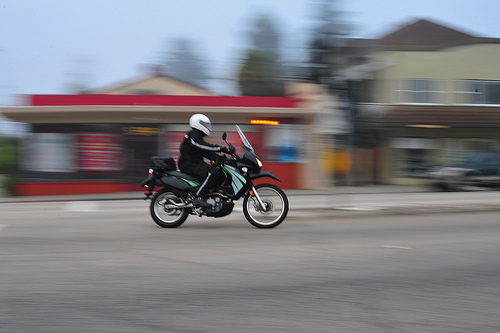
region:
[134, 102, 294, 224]
motorcyclist in the road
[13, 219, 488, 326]
paved road where motorcyclist is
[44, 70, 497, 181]
buildings along side of street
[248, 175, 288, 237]
front tire of a bike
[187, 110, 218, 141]
helmet on a rider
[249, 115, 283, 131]
blurry lights on a building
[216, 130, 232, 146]
sideview mirror on a bike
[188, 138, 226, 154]
stripe on a jacket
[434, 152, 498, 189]
car parked on side of road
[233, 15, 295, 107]
trees behind the buildings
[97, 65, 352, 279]
person riding motorcycle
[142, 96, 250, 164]
person wearing white helmet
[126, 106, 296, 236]
motorcycle is black and green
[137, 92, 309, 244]
motorcycle headlight is on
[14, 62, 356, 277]
motorcycle in front of business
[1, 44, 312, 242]
business has multiple signs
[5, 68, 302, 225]
business is red in color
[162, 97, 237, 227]
rider wearing black clothing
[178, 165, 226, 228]
person wearing black shoes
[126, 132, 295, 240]
motorcycle has green trim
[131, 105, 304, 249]
man riding motorcycle quickly down road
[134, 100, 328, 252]
man wearing white helmet riding motorcycle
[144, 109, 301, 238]
man riding a black bike with blue and green designs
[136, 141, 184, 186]
pack behind bikes rider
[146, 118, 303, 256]
man on motorcycle wearing black jacket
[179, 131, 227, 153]
reflectors on the mans jacket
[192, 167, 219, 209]
reflector on mans pants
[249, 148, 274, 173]
motorcycle with headlight on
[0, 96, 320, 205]
man riding past red and brown store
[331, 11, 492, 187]
yellow and brown house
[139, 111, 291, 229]
A person on a motorcycle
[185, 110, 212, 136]
A person with a white helmet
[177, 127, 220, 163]
A shirt with a white stripe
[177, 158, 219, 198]
Pants with a white stripe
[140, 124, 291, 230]
A black, green, and white motorcycle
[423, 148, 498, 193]
A blurry vehicle in the background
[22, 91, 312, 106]
A building with a red roof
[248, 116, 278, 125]
Blurry orange lights in the background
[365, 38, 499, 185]
A blurry yellow house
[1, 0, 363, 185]
Blurry trees in the background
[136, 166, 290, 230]
a motorcycle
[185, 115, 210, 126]
a white helmet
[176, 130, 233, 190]
a person riding a motorcycle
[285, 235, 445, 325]
the street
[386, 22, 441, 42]
a roof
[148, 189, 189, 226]
back tire of the motorcycle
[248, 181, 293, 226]
front tire of the motorcycle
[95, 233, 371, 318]
the street is grey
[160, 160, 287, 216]
the motorcycle is black and green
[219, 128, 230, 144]
small mirror